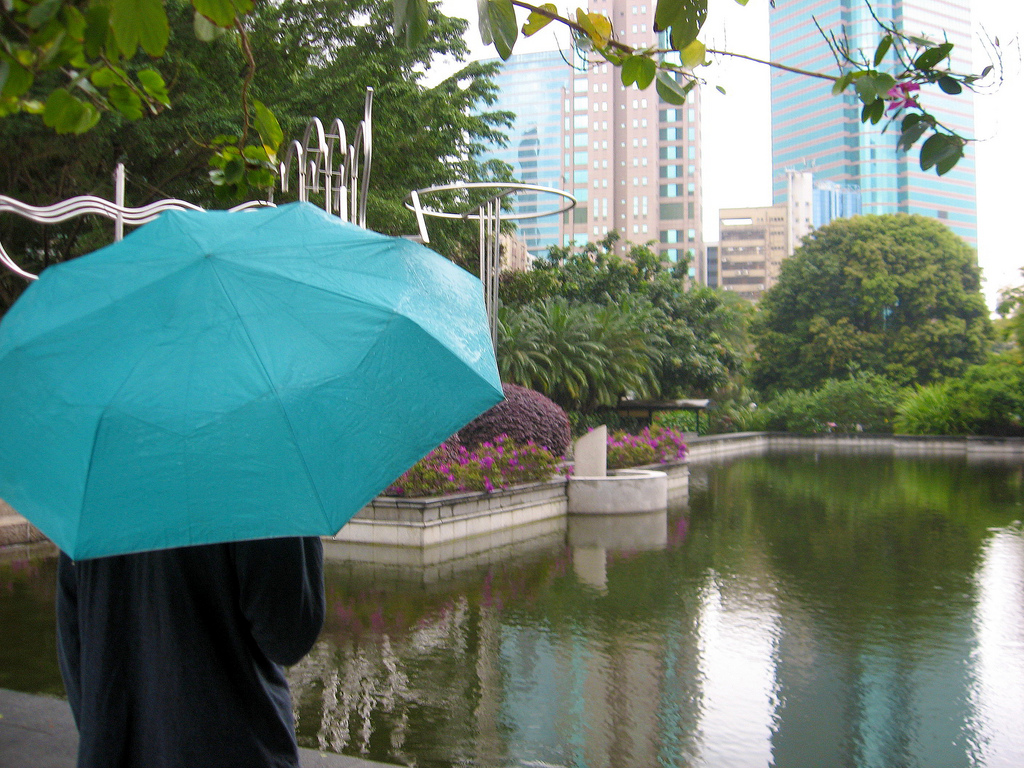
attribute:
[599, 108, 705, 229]
building — tall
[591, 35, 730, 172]
building — tall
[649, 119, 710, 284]
building — tall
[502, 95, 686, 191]
building — tall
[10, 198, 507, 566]
umbrella — blue, wide open green 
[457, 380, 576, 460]
bush — purple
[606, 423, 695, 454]
flowers —  pink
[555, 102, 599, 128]
building — window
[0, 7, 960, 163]
tree — branches 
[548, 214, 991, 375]
bush — purple flowery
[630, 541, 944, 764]
water — clear open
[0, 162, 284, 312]
sculpture — wavy, metal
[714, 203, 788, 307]
building — red